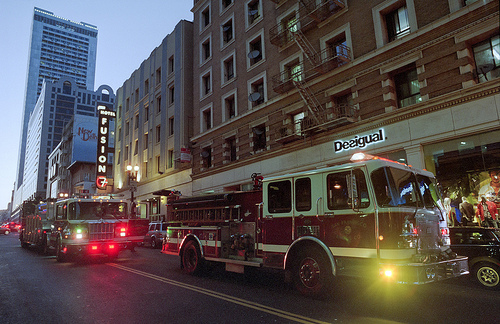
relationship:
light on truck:
[375, 259, 401, 283] [166, 159, 466, 288]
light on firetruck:
[91, 241, 116, 254] [21, 196, 128, 261]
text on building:
[325, 131, 401, 146] [193, 0, 500, 262]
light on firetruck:
[73, 227, 84, 235] [21, 196, 128, 261]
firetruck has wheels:
[21, 196, 128, 261] [37, 234, 68, 258]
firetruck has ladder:
[166, 159, 466, 288] [168, 205, 243, 223]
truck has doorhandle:
[166, 159, 466, 288] [314, 191, 326, 229]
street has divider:
[0, 230, 396, 324] [96, 261, 310, 318]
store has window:
[192, 94, 500, 218] [422, 141, 499, 228]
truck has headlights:
[166, 159, 466, 288] [391, 194, 468, 286]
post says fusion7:
[93, 103, 117, 191] [96, 104, 110, 190]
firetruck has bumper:
[21, 196, 128, 261] [58, 237, 134, 245]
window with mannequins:
[422, 141, 499, 228] [443, 189, 496, 226]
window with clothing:
[422, 141, 499, 228] [444, 199, 499, 227]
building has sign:
[114, 20, 193, 231] [93, 103, 117, 191]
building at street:
[13, 2, 99, 222] [0, 230, 396, 324]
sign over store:
[334, 129, 388, 153] [192, 94, 500, 218]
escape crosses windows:
[272, 0, 362, 137] [192, 0, 497, 175]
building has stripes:
[114, 20, 193, 231] [115, 14, 190, 182]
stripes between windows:
[115, 14, 190, 182] [114, 16, 187, 195]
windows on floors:
[192, 0, 497, 175] [193, 0, 500, 262]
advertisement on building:
[72, 113, 116, 160] [47, 116, 115, 203]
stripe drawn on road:
[106, 261, 325, 321] [6, 217, 457, 319]